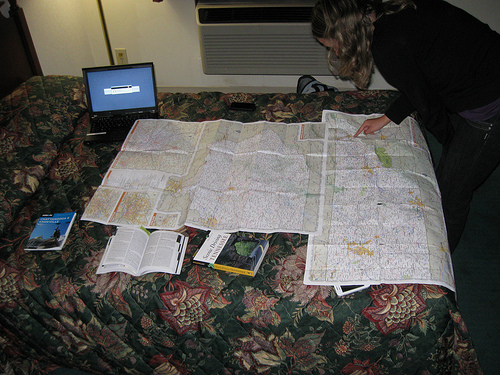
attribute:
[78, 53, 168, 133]
laptop — open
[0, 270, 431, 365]
bed — full size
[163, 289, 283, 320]
quilt — colorful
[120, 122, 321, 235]
map — open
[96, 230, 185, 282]
book — open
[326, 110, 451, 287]
map — open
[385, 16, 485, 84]
top — black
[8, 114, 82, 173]
comforter — floral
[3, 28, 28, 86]
headboard — brown, wood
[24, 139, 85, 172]
bed spread — floral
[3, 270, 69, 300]
bedspread — flower print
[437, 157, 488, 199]
jeans — gray